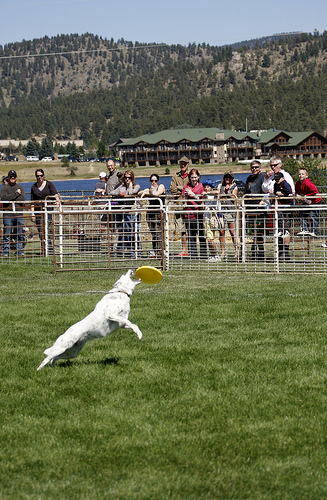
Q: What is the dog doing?
A: Catching frisbee.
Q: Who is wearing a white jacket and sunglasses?
A: Man.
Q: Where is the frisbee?
A: Dog's mouth.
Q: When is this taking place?
A: Daytime.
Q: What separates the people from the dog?
A: Fence.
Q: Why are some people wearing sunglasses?
A: Protecting eyes.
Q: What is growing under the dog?
A: Grass.